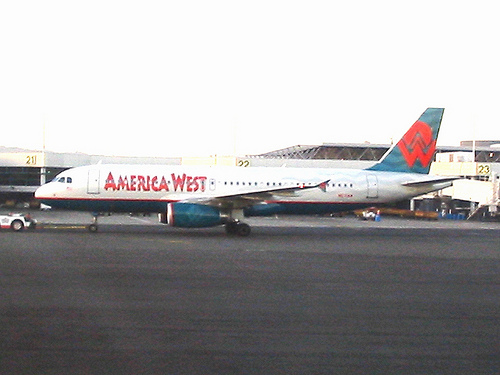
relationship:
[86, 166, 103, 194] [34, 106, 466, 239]
door part of airplane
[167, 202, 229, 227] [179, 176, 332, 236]
engine hanging on wing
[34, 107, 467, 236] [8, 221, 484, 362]
airliner on tarmac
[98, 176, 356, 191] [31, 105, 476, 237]
windows on aircraft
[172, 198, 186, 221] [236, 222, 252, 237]
part of tire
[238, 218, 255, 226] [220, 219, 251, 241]
edge of wheel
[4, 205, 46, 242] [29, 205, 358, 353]
car on runway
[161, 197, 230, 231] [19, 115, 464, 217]
booster jet on plane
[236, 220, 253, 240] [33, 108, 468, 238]
tire on plane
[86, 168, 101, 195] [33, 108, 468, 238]
door on plane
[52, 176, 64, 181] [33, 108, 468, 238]
windshield on plane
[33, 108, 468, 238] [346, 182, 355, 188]
plane has window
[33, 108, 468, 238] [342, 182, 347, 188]
plane has window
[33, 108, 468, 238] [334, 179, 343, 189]
plane has window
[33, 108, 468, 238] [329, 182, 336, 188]
plane has window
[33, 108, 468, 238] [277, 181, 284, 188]
plane has window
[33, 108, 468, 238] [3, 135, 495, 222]
plane in airport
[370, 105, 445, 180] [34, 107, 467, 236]
tail on airliner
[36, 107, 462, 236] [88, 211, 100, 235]
airliner has landing gear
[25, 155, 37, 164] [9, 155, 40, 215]
21 on building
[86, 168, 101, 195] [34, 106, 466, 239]
door of airplane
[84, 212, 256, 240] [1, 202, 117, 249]
equipment pulling plane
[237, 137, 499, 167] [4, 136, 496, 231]
roof of terminal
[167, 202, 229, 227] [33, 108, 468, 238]
engine of plane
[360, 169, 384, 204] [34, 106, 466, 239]
back door of airplane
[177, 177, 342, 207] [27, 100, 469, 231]
wing on plane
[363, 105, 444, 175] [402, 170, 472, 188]
tail on wing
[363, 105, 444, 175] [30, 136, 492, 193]
tail of plane